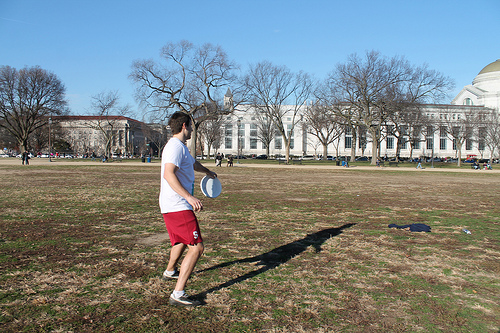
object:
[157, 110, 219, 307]
person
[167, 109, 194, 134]
hair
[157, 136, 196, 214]
shirt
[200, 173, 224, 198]
frisbee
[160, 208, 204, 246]
shorts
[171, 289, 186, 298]
socks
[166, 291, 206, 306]
shoes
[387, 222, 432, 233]
clothing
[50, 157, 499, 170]
grass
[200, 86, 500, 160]
building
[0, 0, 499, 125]
sky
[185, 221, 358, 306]
shadow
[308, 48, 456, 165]
trees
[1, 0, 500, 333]
park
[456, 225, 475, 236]
water bottle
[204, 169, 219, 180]
hand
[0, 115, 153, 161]
small building